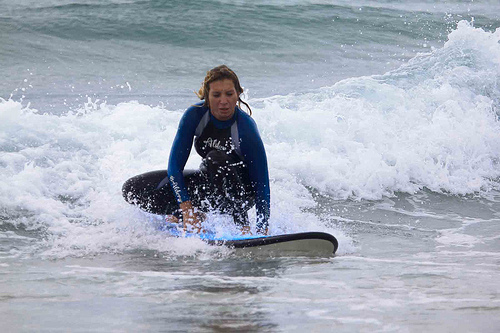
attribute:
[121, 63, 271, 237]
woman — happy, wet, surfing, close, outside during day, enjoying day, squatting down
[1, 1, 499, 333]
ocean — splashing, wavy, assertive, aggressive, lively, zealous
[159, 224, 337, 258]
surfboard — blue white, black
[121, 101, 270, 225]
wetsuit — blue, black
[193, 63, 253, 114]
hair — wet, long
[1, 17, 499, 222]
wave — cresting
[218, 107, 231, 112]
mouth — slightly open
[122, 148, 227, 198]
knees — bent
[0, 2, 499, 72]
ripples — small